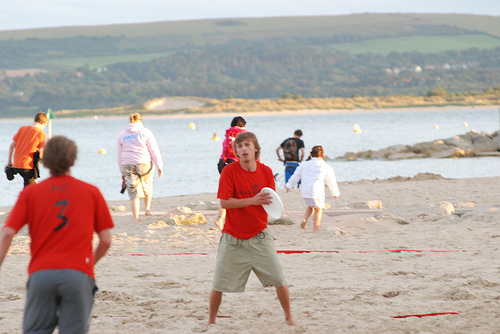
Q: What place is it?
A: It is a beach.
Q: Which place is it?
A: It is a beach.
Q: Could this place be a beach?
A: Yes, it is a beach.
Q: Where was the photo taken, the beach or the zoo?
A: It was taken at the beach.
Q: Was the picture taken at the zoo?
A: No, the picture was taken in the beach.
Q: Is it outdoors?
A: Yes, it is outdoors.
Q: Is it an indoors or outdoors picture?
A: It is outdoors.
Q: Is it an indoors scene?
A: No, it is outdoors.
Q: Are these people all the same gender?
A: No, they are both male and female.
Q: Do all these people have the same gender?
A: No, they are both male and female.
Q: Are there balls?
A: No, there are no balls.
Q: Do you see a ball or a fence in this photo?
A: No, there are no balls or fences.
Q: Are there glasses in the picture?
A: No, there are no glasses.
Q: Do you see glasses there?
A: No, there are no glasses.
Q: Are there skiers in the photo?
A: No, there are no skiers.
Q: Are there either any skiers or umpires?
A: No, there are no skiers or umpires.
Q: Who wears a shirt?
A: The man wears a shirt.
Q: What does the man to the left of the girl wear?
A: The man wears a shirt.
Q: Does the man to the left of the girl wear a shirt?
A: Yes, the man wears a shirt.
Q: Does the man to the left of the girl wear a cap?
A: No, the man wears a shirt.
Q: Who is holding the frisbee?
A: The man is holding the frisbee.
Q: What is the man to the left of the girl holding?
A: The man is holding the frisbee.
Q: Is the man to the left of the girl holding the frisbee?
A: Yes, the man is holding the frisbee.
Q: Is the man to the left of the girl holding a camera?
A: No, the man is holding the frisbee.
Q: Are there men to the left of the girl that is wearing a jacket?
A: Yes, there is a man to the left of the girl.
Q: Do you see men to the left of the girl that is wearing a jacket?
A: Yes, there is a man to the left of the girl.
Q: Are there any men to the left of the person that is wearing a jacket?
A: Yes, there is a man to the left of the girl.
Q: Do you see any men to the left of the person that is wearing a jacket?
A: Yes, there is a man to the left of the girl.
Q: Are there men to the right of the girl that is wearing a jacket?
A: No, the man is to the left of the girl.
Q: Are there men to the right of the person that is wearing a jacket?
A: No, the man is to the left of the girl.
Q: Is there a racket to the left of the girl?
A: No, there is a man to the left of the girl.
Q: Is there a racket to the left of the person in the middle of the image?
A: No, there is a man to the left of the girl.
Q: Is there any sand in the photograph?
A: Yes, there is sand.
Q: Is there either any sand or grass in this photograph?
A: Yes, there is sand.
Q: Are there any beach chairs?
A: No, there are no beach chairs.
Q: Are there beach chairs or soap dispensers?
A: No, there are no beach chairs or soap dispensers.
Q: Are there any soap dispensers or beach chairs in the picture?
A: No, there are no beach chairs or soap dispensers.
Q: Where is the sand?
A: The sand is on the beach.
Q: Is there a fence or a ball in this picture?
A: No, there are no fences or balls.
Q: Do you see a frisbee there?
A: Yes, there is a frisbee.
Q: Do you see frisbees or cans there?
A: Yes, there is a frisbee.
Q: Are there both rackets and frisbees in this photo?
A: No, there is a frisbee but no rackets.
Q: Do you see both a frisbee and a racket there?
A: No, there is a frisbee but no rackets.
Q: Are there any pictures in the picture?
A: No, there are no pictures.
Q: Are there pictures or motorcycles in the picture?
A: No, there are no pictures or motorcycles.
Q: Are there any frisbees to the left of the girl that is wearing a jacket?
A: Yes, there is a frisbee to the left of the girl.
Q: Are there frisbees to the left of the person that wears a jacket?
A: Yes, there is a frisbee to the left of the girl.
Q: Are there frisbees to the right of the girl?
A: No, the frisbee is to the left of the girl.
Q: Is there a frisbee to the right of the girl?
A: No, the frisbee is to the left of the girl.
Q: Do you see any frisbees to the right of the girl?
A: No, the frisbee is to the left of the girl.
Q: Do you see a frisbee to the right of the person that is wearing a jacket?
A: No, the frisbee is to the left of the girl.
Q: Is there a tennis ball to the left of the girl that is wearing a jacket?
A: No, there is a frisbee to the left of the girl.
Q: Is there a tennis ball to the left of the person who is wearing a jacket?
A: No, there is a frisbee to the left of the girl.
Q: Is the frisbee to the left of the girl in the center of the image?
A: Yes, the frisbee is to the left of the girl.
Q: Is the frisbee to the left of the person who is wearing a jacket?
A: Yes, the frisbee is to the left of the girl.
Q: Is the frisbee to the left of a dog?
A: No, the frisbee is to the left of the girl.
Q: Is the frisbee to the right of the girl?
A: No, the frisbee is to the left of the girl.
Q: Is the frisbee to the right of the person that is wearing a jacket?
A: No, the frisbee is to the left of the girl.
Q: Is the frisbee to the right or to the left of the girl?
A: The frisbee is to the left of the girl.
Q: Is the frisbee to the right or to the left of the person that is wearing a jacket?
A: The frisbee is to the left of the girl.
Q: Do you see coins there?
A: No, there are no coins.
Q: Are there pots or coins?
A: No, there are no coins or pots.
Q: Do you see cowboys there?
A: No, there are no cowboys.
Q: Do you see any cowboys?
A: No, there are no cowboys.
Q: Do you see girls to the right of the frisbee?
A: Yes, there is a girl to the right of the frisbee.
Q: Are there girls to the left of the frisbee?
A: No, the girl is to the right of the frisbee.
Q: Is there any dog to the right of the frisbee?
A: No, there is a girl to the right of the frisbee.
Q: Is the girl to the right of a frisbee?
A: Yes, the girl is to the right of a frisbee.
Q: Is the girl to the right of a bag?
A: No, the girl is to the right of a frisbee.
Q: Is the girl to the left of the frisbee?
A: No, the girl is to the right of the frisbee.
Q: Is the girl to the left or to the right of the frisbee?
A: The girl is to the right of the frisbee.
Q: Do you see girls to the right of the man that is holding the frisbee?
A: Yes, there is a girl to the right of the man.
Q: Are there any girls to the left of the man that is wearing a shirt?
A: No, the girl is to the right of the man.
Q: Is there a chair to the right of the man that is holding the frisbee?
A: No, there is a girl to the right of the man.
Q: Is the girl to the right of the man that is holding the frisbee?
A: Yes, the girl is to the right of the man.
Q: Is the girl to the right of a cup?
A: No, the girl is to the right of the man.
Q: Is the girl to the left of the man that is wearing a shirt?
A: No, the girl is to the right of the man.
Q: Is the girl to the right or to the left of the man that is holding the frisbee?
A: The girl is to the right of the man.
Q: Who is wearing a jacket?
A: The girl is wearing a jacket.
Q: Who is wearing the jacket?
A: The girl is wearing a jacket.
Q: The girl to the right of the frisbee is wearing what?
A: The girl is wearing a jacket.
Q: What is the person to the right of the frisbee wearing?
A: The girl is wearing a jacket.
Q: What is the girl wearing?
A: The girl is wearing a jacket.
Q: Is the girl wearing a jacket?
A: Yes, the girl is wearing a jacket.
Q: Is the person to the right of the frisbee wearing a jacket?
A: Yes, the girl is wearing a jacket.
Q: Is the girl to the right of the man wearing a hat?
A: No, the girl is wearing a jacket.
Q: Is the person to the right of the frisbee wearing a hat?
A: No, the girl is wearing a jacket.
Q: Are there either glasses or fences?
A: No, there are no fences or glasses.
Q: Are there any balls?
A: No, there are no balls.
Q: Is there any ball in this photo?
A: No, there are no balls.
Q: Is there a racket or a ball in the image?
A: No, there are no balls or rackets.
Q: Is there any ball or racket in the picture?
A: No, there are no balls or rackets.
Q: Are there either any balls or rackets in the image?
A: No, there are no balls or rackets.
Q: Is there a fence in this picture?
A: No, there are no fences.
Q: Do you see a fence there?
A: No, there are no fences.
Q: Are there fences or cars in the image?
A: No, there are no fences or cars.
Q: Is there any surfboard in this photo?
A: No, there are no surfboards.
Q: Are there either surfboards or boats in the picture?
A: No, there are no surfboards or boats.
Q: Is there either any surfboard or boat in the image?
A: No, there are no surfboards or boats.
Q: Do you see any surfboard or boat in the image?
A: No, there are no surfboards or boats.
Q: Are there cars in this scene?
A: No, there are no cars.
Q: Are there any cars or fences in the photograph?
A: No, there are no cars or fences.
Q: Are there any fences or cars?
A: No, there are no cars or fences.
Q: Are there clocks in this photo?
A: No, there are no clocks.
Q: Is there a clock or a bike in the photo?
A: No, there are no clocks or bikes.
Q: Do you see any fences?
A: No, there are no fences.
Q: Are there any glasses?
A: No, there are no glasses.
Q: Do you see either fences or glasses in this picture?
A: No, there are no glasses or fences.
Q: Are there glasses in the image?
A: No, there are no glasses.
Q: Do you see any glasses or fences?
A: No, there are no glasses or fences.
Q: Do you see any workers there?
A: No, there are no workers.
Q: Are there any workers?
A: No, there are no workers.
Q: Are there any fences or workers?
A: No, there are no workers or fences.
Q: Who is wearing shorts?
A: The man is wearing shorts.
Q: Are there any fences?
A: No, there are no fences.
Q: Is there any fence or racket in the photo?
A: No, there are no fences or rackets.